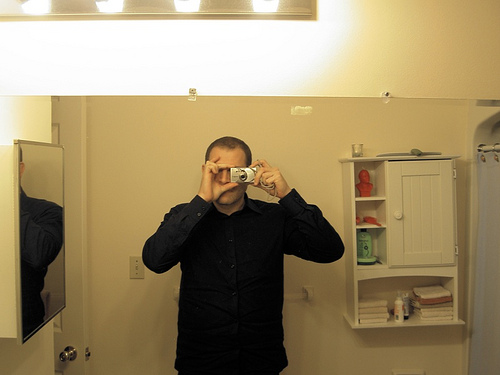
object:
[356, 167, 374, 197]
bust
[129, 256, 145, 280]
lightswitch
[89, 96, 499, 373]
wall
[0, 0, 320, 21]
light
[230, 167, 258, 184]
camera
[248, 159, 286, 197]
hand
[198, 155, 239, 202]
hand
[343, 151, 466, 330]
shelving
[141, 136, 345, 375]
guy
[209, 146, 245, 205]
light skinned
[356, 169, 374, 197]
statue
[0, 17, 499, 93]
wall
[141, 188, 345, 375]
shirt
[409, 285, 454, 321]
towels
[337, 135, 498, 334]
washclothes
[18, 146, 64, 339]
reflection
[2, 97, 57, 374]
wall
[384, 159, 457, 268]
door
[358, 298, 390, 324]
towels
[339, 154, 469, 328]
bathroom shelf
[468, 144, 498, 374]
shower curtain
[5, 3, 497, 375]
bathroom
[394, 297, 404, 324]
bottle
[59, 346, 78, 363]
door knob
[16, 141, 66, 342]
mirror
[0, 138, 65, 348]
cabinet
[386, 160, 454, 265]
cupboard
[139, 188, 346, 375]
black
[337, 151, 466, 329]
cabinet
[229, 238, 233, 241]
button down